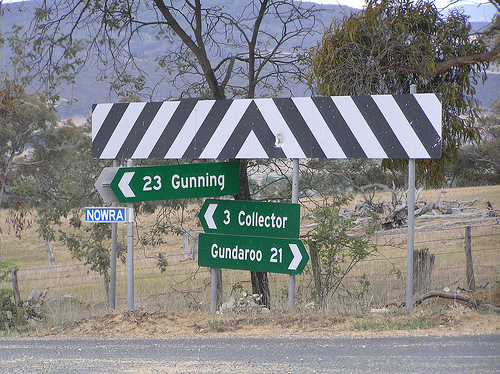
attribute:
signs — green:
[101, 157, 321, 324]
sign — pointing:
[197, 230, 310, 280]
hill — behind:
[3, 187, 490, 299]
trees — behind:
[299, 3, 492, 187]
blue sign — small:
[85, 205, 127, 222]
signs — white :
[102, 165, 311, 285]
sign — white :
[77, 80, 494, 178]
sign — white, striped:
[95, 90, 423, 170]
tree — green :
[13, 0, 488, 312]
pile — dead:
[325, 178, 490, 250]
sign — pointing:
[193, 234, 315, 276]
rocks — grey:
[215, 289, 276, 319]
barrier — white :
[94, 94, 440, 314]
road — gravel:
[16, 290, 498, 372]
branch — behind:
[309, 176, 496, 231]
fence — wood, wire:
[339, 230, 451, 295]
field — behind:
[1, 182, 497, 333]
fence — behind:
[0, 222, 498, 313]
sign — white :
[164, 93, 446, 161]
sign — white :
[83, 206, 131, 220]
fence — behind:
[314, 232, 409, 303]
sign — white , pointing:
[195, 197, 302, 237]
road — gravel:
[333, 331, 375, 351]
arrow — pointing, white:
[284, 240, 307, 272]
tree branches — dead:
[343, 181, 475, 234]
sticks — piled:
[355, 180, 478, 226]